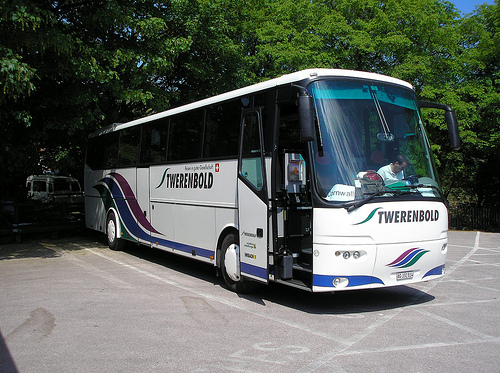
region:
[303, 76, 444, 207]
the windshield of a bus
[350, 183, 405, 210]
a black windshield wiper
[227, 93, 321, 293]
an open door on the side of a bus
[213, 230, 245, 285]
a wheel with a white hub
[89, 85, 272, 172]
passenger windows on a bus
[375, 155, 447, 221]
a bus driver wearing a white shirt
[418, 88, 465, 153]
the side view mirror on a bus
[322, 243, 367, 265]
headlights on a vehicle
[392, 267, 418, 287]
a license plate on a vehicle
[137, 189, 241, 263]
the undercarriage cargo holds on a bus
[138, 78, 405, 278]
this is a bus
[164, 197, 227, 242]
the bus is white in color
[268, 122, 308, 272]
this is the door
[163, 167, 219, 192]
this is a writing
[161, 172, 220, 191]
the writing is in black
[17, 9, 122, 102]
this is a tree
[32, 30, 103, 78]
the leaves are green in color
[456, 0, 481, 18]
the sky is blue in color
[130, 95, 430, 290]
the bus is parked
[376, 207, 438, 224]
The word TWERENBOLD.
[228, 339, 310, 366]
Faint E S on the ground.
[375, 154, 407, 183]
A brown haired man in a white shirt driving a bus.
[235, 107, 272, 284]
Open door of a bus.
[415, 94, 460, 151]
Black rear view mirror on the driver side of the bus.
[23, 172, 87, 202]
A white van past the trees.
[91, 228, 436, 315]
Black shadow under a bus.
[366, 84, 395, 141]
Two windshield wipers on the windshield of the bus.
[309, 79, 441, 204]
A large clear windshield on a bus.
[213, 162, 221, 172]
Red square with white cross inside.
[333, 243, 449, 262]
small round headlights on front of bus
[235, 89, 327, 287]
bus door is open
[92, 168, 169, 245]
green, blue, and purple stripes on bus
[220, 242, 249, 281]
white hub caps on bus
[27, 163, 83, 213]
white van in the background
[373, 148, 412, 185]
person slumped in driver's seat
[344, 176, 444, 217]
windshield wipers on front of bus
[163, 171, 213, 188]
Twerenbold written on side of bus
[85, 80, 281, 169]
bank of tinted windows on side of bus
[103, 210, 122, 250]
back wheel of a bus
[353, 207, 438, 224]
logo on the front of a bus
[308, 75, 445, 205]
bus windshield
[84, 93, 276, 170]
side windows of the bus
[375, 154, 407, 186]
person sitting in driver's seat of bus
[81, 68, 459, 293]
parked white bus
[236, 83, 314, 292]
open door of a bus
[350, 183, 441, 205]
folded black windshield wipers